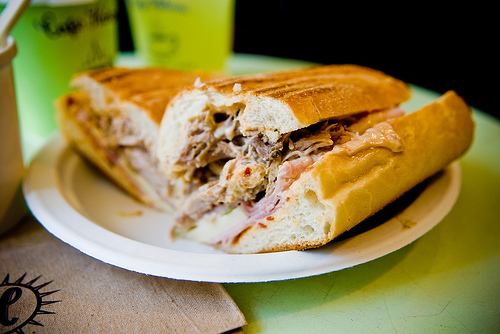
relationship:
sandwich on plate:
[60, 65, 473, 255] [24, 133, 459, 284]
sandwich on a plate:
[60, 65, 473, 255] [24, 133, 459, 284]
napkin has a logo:
[3, 222, 247, 333] [0, 273, 63, 332]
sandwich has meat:
[60, 65, 473, 255] [173, 110, 403, 244]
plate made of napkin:
[24, 133, 459, 284] [0, 232, 247, 333]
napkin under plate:
[3, 222, 247, 333] [24, 133, 459, 284]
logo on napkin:
[0, 273, 63, 332] [3, 222, 247, 333]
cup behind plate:
[1, 0, 119, 137] [24, 133, 459, 284]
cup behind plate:
[128, 0, 233, 72] [24, 133, 459, 284]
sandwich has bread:
[60, 65, 473, 255] [54, 64, 475, 251]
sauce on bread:
[223, 185, 288, 245] [54, 64, 475, 251]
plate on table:
[24, 133, 459, 284] [3, 52, 499, 333]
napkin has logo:
[3, 222, 247, 333] [0, 273, 63, 332]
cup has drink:
[1, 0, 119, 137] [1, 5, 116, 133]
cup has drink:
[128, 0, 233, 72] [125, 0, 235, 77]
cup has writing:
[1, 0, 119, 137] [32, 3, 117, 40]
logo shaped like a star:
[0, 273, 63, 332] [0, 275, 63, 332]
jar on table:
[0, 28, 28, 243] [3, 52, 499, 333]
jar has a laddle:
[0, 28, 28, 243] [0, 1, 35, 45]